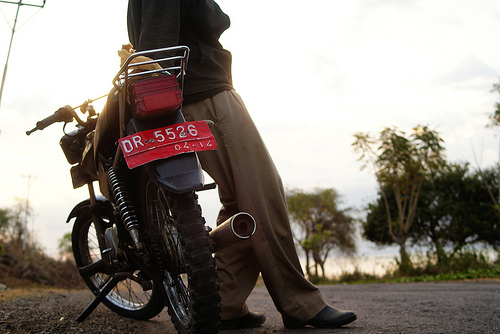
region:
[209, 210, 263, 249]
the exhast on the motorcycle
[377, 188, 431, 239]
tree branches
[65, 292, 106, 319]
the kickstand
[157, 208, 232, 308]
the back tire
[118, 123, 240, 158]
a red and white license plate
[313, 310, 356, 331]
person is wearing blak shoes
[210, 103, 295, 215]
person is wearing tanned pants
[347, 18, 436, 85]
clouds in the sky are white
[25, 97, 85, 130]
handle bar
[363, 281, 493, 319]
the road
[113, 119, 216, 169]
license plate is red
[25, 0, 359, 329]
person is leaning on motorcycle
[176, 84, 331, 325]
man is wearing khakis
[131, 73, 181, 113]
tail light is red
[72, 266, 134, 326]
motorcycle is leaning on kickstand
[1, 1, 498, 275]
the sky is bright with few clouds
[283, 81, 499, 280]
green trees in background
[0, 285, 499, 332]
the road is made of gravel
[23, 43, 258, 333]
black motorcycle on street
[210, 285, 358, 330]
person has on black boots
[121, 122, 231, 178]
Red license plate with white writing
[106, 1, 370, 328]
A man leaning against the motorcycle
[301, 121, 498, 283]
Trees on the side of the road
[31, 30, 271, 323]
Black motorcycle parked on the shoulder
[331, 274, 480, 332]
Black asphalt road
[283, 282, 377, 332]
Black shoes of the man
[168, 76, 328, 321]
A man wearing khaki pants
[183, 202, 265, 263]
Silver exhaust pipe of the motorcycle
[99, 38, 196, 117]
Red light and carrier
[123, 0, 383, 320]
A man waiting on the shoulder of the road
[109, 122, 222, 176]
A red liscense plate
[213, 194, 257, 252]
exhaust for the bike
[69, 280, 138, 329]
kickstand in the gravel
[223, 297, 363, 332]
a black pair of boots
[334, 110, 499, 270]
trees on the roadside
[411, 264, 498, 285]
Grass across the street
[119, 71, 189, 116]
the red tail light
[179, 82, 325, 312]
a brown pair of slacks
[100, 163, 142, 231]
The shocks on the bike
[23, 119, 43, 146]
The handle of the brake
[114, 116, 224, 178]
license plate of the motorcycle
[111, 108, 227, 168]
license plate of the bike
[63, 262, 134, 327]
kick stand of a motorcycle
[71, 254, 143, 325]
kick stand of the bike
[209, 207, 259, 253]
exhaust pipe of the motorcycle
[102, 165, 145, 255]
shock absorber on the bike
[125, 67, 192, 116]
a taillight on the bike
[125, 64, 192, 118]
a tail light on the motorcycle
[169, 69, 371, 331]
man leaning on a bike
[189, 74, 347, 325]
a pair of tan pants